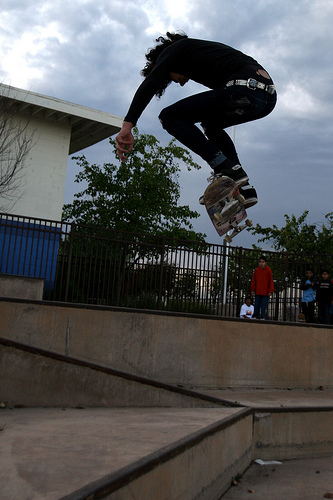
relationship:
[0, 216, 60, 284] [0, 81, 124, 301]
blue wall in building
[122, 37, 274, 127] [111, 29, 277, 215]
black shirt on skateboarder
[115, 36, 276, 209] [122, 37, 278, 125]
boy wearing shirt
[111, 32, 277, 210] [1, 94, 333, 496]
boy at a park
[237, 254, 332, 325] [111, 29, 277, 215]
boys watching skateboarder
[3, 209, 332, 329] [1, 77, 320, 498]
fence around park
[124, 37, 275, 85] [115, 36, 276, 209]
black shirt on boy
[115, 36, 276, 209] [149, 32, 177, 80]
boy has hair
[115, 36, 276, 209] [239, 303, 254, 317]
boy wearing top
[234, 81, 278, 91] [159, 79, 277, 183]
belt holding pants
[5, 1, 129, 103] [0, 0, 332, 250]
blue sky with clouds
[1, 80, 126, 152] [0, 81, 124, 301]
roof of building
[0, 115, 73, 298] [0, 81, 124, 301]
wall of building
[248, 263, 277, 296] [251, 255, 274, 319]
red jacket on boy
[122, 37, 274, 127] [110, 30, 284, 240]
black shirt on kid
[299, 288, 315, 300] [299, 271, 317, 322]
jacket on boys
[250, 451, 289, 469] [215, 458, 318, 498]
paper on floor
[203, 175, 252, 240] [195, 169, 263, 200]
skateboard under feet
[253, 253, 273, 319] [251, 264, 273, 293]
boy wearing sweater